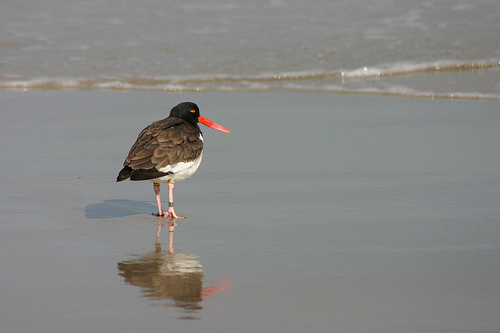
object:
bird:
[115, 100, 232, 220]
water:
[0, 2, 500, 93]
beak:
[199, 115, 233, 133]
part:
[7, 80, 32, 87]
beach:
[2, 88, 500, 333]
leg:
[163, 179, 188, 220]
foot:
[164, 202, 187, 220]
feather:
[154, 123, 186, 144]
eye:
[189, 108, 196, 115]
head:
[169, 100, 200, 122]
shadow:
[81, 195, 167, 221]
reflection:
[116, 216, 236, 323]